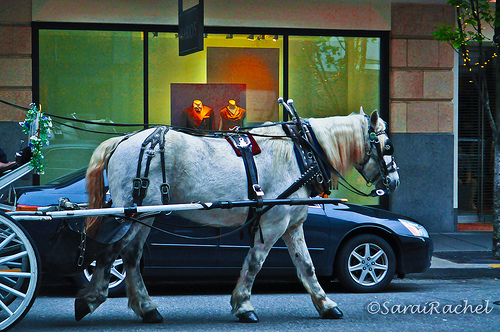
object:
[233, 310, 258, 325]
hoof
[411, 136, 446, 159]
wall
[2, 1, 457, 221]
building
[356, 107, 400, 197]
head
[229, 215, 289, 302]
legs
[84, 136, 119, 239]
horse tail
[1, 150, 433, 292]
car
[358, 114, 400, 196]
bridle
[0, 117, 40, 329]
chariiot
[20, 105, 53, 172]
flowers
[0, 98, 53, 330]
carriage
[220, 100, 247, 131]
mannequins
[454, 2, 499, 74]
christmas lights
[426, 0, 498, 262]
tree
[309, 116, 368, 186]
mane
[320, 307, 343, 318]
hoof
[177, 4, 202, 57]
sign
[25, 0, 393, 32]
roof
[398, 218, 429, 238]
headlight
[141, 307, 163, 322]
hoove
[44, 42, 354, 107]
wall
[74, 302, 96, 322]
black hooves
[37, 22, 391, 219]
window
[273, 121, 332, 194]
harness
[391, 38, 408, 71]
bricks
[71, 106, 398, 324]
horse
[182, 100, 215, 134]
mannequin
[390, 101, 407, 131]
stone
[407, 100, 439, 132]
stone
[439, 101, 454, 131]
stone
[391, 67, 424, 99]
stone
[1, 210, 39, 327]
carriage wheel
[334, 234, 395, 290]
wheel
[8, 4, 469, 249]
store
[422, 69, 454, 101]
brick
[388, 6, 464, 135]
wall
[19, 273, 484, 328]
street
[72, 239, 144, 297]
wheel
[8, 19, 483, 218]
storefront